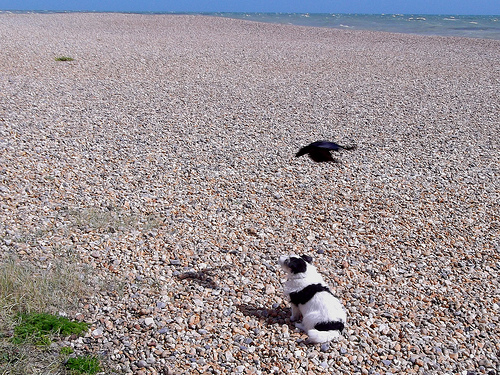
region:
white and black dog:
[273, 247, 347, 357]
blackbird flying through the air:
[293, 136, 369, 168]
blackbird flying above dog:
[269, 132, 374, 346]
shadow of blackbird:
[168, 253, 230, 293]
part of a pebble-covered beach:
[51, 74, 152, 201]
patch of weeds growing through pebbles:
[54, 51, 76, 71]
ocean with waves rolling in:
[385, 12, 479, 35]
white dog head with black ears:
[275, 251, 320, 278]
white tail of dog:
[303, 326, 340, 345]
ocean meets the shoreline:
[297, 12, 449, 51]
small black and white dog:
[261, 243, 359, 351]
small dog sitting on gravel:
[270, 242, 353, 357]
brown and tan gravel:
[361, 264, 459, 336]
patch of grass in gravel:
[9, 305, 111, 358]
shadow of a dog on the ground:
[219, 293, 291, 330]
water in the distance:
[224, 7, 498, 65]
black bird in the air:
[267, 137, 370, 174]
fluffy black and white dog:
[269, 242, 352, 354]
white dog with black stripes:
[277, 250, 351, 350]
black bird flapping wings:
[282, 130, 357, 171]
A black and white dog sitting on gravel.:
[260, 253, 350, 339]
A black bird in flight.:
[290, 130, 360, 165]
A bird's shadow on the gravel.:
[165, 260, 235, 290]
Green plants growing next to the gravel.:
[1, 300, 106, 371]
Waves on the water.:
[0, 1, 495, 36]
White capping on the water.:
[5, 0, 495, 30]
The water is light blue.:
[226, 10, 491, 31]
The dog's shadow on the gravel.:
[235, 285, 295, 327]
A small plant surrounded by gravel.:
[47, 46, 77, 66]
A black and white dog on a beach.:
[0, 0, 497, 373]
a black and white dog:
[280, 228, 372, 360]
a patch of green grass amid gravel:
[15, 307, 92, 342]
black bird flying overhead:
[288, 123, 366, 169]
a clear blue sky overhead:
[276, 2, 478, 14]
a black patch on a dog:
[288, 285, 334, 299]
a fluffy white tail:
[300, 322, 334, 342]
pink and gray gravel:
[99, 94, 260, 198]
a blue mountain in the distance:
[322, 11, 488, 31]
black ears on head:
[291, 248, 325, 268]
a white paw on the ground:
[291, 310, 301, 323]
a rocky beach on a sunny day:
[1, 11, 281, 248]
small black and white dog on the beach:
[273, 251, 348, 345]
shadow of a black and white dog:
[234, 300, 292, 329]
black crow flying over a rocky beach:
[293, 138, 358, 165]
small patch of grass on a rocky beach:
[55, 55, 75, 64]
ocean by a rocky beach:
[246, 10, 498, 35]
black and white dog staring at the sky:
[276, 252, 349, 344]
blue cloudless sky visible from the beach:
[1, 3, 496, 12]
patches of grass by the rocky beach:
[0, 253, 105, 372]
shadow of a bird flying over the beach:
[176, 263, 226, 290]